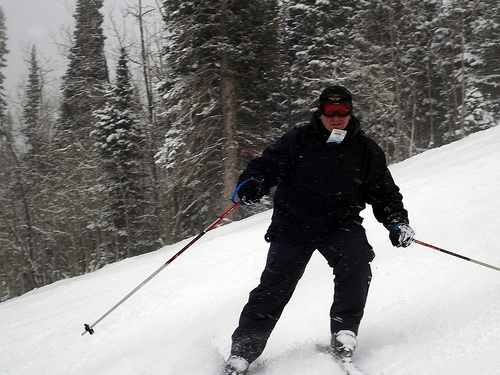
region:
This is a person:
[147, 74, 370, 371]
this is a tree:
[33, 131, 118, 276]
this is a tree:
[83, 73, 166, 271]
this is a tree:
[10, 52, 92, 277]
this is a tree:
[161, 9, 269, 244]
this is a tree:
[289, 5, 409, 186]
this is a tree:
[388, 19, 447, 145]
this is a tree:
[430, 8, 487, 148]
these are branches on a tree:
[135, 113, 232, 190]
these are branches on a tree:
[88, 198, 127, 260]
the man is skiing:
[162, 96, 442, 361]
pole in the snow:
[79, 290, 186, 337]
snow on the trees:
[152, 123, 193, 190]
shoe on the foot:
[318, 322, 359, 365]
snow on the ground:
[421, 309, 470, 357]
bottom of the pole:
[78, 315, 103, 337]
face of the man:
[314, 83, 362, 138]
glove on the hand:
[391, 223, 411, 250]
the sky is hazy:
[39, 20, 59, 48]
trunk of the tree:
[212, 109, 238, 172]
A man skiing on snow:
[246, 110, 414, 349]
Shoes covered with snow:
[211, 330, 362, 372]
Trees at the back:
[171, 65, 249, 175]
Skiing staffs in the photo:
[117, 207, 497, 286]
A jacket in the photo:
[298, 178, 360, 253]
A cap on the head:
[320, 80, 350, 108]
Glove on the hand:
[230, 179, 275, 209]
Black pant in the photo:
[269, 243, 302, 296]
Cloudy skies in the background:
[53, 7, 89, 47]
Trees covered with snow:
[167, 36, 292, 128]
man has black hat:
[325, 77, 350, 122]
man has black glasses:
[319, 103, 366, 130]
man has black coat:
[226, 120, 424, 252]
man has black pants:
[221, 249, 411, 365]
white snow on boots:
[325, 318, 370, 360]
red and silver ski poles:
[82, 204, 233, 326]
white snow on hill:
[61, 226, 290, 368]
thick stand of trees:
[9, 0, 412, 287]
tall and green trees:
[117, 12, 461, 152]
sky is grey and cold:
[1, 7, 154, 77]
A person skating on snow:
[200, 90, 391, 351]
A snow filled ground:
[381, 247, 473, 359]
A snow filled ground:
[12, 285, 197, 363]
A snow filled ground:
[412, 155, 497, 232]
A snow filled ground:
[120, 244, 251, 325]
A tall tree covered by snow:
[94, 58, 142, 248]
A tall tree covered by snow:
[165, 1, 262, 202]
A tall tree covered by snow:
[64, 5, 108, 263]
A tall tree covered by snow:
[340, 0, 424, 148]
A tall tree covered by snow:
[427, 11, 498, 135]